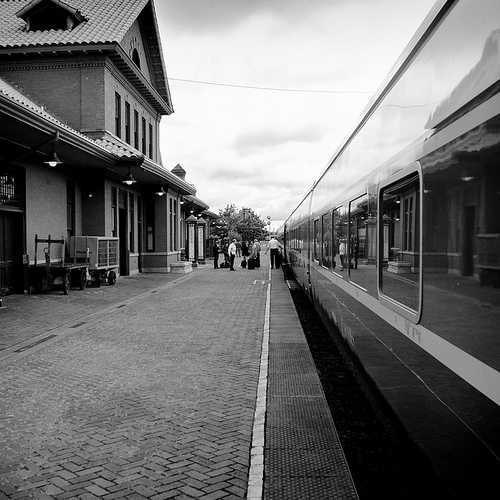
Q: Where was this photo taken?
A: At a train station.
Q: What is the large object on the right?
A: A train.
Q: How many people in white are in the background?
A: Two.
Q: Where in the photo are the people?
A: The background.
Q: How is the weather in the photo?
A: Cloudy.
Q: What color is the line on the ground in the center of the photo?
A: White.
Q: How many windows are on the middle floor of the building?
A: Five.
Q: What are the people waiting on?
A: The train.